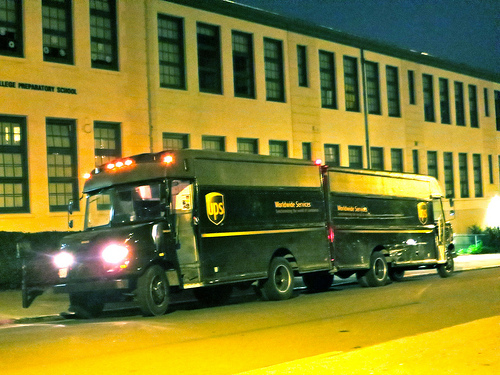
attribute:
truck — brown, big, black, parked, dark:
[72, 144, 328, 291]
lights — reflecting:
[97, 239, 139, 263]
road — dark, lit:
[232, 312, 310, 337]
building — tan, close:
[59, 25, 475, 169]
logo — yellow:
[202, 193, 240, 226]